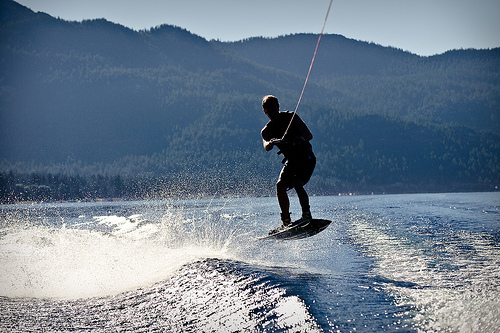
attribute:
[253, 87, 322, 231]
person — jet skiing, surfing, wake-boarding, dark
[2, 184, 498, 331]
water — blue, body, splashed, splashing, white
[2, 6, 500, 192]
vegetation — dark green, green, full of trees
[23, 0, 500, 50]
sky — grey, blue color, clear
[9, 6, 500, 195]
mountain — on the horizon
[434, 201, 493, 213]
sunlight reflection — glaring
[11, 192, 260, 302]
sea foam — white, small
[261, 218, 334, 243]
surfboard — dark